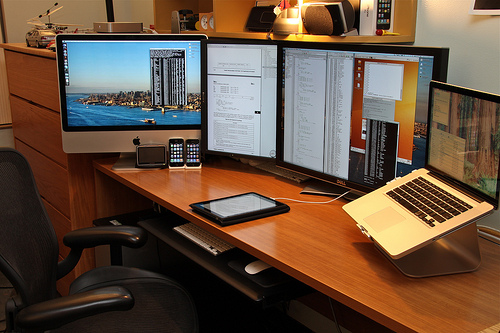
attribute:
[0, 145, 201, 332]
chair — black, mesh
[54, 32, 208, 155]
monitor — apple, on, large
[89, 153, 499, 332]
desk — wood, wooden, brown, large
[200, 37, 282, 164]
monitor — on, large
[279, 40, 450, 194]
monitor — on, large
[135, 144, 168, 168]
smartphone — mobile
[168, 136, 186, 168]
smartphone — mobile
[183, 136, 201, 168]
smartphone — mobile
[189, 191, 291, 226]
tablet — charging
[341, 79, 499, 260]
laptop — mounted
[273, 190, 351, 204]
cord — white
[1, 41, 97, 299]
file cabinet — wooden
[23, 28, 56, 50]
car — toy, model